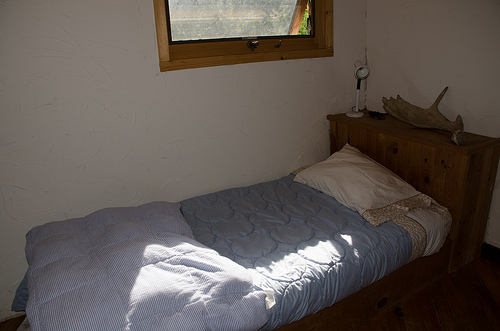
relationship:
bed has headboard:
[10, 161, 455, 330] [321, 114, 484, 264]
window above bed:
[146, 0, 334, 74] [12, 104, 484, 330]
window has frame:
[146, 0, 334, 74] [157, 34, 331, 71]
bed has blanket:
[12, 104, 484, 330] [273, 210, 359, 300]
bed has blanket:
[12, 104, 484, 330] [27, 197, 219, 327]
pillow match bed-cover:
[290, 143, 438, 227] [180, 160, 451, 330]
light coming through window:
[130, 233, 331, 313] [146, 0, 334, 74]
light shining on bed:
[130, 233, 331, 313] [12, 104, 484, 330]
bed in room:
[12, 104, 484, 330] [15, 15, 482, 317]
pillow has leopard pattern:
[290, 143, 438, 227] [365, 195, 427, 226]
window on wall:
[146, 0, 334, 74] [21, 21, 148, 195]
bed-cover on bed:
[181, 180, 426, 329] [12, 104, 484, 330]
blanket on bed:
[23, 200, 271, 331] [12, 104, 484, 330]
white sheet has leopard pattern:
[392, 203, 450, 262] [409, 223, 426, 253]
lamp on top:
[343, 59, 371, 119] [323, 106, 483, 151]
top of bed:
[323, 106, 483, 151] [12, 104, 484, 330]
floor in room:
[385, 294, 485, 326] [15, 15, 482, 317]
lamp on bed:
[343, 59, 371, 119] [12, 104, 484, 330]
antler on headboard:
[379, 85, 467, 146] [321, 114, 484, 264]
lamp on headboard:
[347, 58, 372, 119] [324, 102, 493, 165]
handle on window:
[244, 33, 265, 48] [147, 3, 341, 78]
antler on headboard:
[381, 85, 474, 147] [323, 106, 498, 217]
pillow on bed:
[290, 143, 438, 227] [23, 162, 451, 329]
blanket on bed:
[23, 200, 271, 331] [23, 162, 451, 329]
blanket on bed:
[24, 163, 407, 328] [23, 162, 451, 329]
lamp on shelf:
[343, 59, 371, 119] [317, 103, 391, 133]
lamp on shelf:
[343, 59, 371, 119] [321, 99, 493, 186]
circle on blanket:
[266, 184, 303, 209] [24, 163, 407, 328]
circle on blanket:
[287, 194, 320, 221] [24, 163, 407, 328]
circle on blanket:
[314, 211, 346, 236] [24, 163, 407, 328]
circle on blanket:
[330, 222, 372, 250] [24, 163, 407, 328]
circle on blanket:
[270, 218, 315, 241] [24, 163, 407, 328]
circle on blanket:
[250, 203, 290, 229] [24, 163, 407, 328]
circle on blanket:
[230, 190, 275, 211] [23, 179, 411, 330]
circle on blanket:
[260, 247, 314, 281] [24, 163, 407, 328]